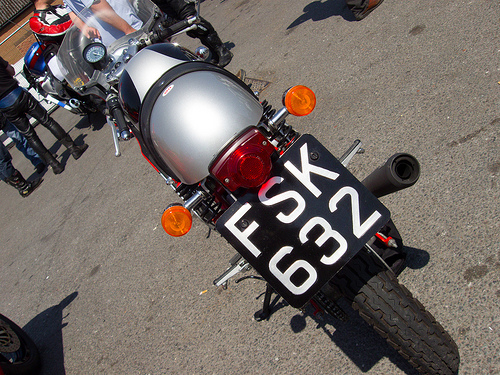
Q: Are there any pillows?
A: No, there are no pillows.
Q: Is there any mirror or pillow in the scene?
A: No, there are no pillows or mirrors.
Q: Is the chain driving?
A: Yes, the chain is driving.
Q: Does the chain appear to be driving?
A: Yes, the chain is driving.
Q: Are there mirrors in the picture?
A: No, there are no mirrors.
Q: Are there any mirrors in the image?
A: No, there are no mirrors.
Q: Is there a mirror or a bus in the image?
A: No, there are no mirrors or buses.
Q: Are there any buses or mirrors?
A: No, there are no mirrors or buses.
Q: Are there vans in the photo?
A: No, there are no vans.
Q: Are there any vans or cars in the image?
A: No, there are no vans or cars.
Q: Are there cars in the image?
A: No, there are no cars.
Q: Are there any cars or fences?
A: No, there are no cars or fences.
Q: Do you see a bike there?
A: Yes, there is a bike.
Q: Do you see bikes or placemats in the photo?
A: Yes, there is a bike.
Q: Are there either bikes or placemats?
A: Yes, there is a bike.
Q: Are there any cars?
A: No, there are no cars.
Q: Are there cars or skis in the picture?
A: No, there are no cars or skis.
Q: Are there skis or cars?
A: No, there are no cars or skis.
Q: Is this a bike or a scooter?
A: This is a bike.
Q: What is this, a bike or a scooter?
A: This is a bike.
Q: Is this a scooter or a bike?
A: This is a bike.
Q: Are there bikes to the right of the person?
A: Yes, there is a bike to the right of the person.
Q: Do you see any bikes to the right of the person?
A: Yes, there is a bike to the right of the person.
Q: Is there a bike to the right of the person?
A: Yes, there is a bike to the right of the person.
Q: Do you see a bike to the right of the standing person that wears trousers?
A: Yes, there is a bike to the right of the person.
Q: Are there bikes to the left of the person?
A: No, the bike is to the right of the person.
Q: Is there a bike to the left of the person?
A: No, the bike is to the right of the person.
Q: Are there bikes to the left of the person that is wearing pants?
A: No, the bike is to the right of the person.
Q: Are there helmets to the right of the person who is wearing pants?
A: No, there is a bike to the right of the person.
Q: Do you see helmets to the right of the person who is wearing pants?
A: No, there is a bike to the right of the person.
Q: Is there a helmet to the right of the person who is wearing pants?
A: No, there is a bike to the right of the person.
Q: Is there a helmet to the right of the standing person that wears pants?
A: No, there is a bike to the right of the person.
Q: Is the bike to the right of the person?
A: Yes, the bike is to the right of the person.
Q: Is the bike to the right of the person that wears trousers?
A: Yes, the bike is to the right of the person.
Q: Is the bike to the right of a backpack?
A: No, the bike is to the right of the person.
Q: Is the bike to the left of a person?
A: No, the bike is to the right of a person.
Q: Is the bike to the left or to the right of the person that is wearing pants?
A: The bike is to the right of the person.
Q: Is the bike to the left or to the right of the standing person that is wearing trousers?
A: The bike is to the right of the person.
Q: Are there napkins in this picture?
A: No, there are no napkins.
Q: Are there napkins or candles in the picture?
A: No, there are no napkins or candles.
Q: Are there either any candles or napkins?
A: No, there are no napkins or candles.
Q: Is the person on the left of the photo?
A: Yes, the person is on the left of the image.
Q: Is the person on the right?
A: No, the person is on the left of the image.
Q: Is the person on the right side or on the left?
A: The person is on the left of the image.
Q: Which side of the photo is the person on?
A: The person is on the left of the image.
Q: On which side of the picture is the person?
A: The person is on the left of the image.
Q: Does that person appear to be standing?
A: Yes, the person is standing.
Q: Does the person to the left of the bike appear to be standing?
A: Yes, the person is standing.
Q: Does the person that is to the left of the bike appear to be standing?
A: Yes, the person is standing.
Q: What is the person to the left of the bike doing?
A: The person is standing.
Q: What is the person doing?
A: The person is standing.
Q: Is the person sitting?
A: No, the person is standing.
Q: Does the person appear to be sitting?
A: No, the person is standing.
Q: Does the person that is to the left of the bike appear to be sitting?
A: No, the person is standing.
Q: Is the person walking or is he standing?
A: The person is standing.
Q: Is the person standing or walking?
A: The person is standing.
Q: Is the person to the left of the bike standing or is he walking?
A: The person is standing.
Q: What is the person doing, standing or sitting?
A: The person is standing.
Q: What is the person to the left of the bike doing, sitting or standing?
A: The person is standing.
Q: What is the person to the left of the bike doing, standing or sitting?
A: The person is standing.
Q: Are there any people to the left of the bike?
A: Yes, there is a person to the left of the bike.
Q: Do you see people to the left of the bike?
A: Yes, there is a person to the left of the bike.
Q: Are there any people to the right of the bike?
A: No, the person is to the left of the bike.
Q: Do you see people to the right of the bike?
A: No, the person is to the left of the bike.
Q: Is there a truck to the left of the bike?
A: No, there is a person to the left of the bike.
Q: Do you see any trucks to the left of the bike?
A: No, there is a person to the left of the bike.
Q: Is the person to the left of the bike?
A: Yes, the person is to the left of the bike.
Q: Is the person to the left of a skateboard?
A: No, the person is to the left of the bike.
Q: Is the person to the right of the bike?
A: No, the person is to the left of the bike.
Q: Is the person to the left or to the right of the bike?
A: The person is to the left of the bike.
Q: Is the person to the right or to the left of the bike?
A: The person is to the left of the bike.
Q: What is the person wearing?
A: The person is wearing trousers.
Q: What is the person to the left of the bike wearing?
A: The person is wearing trousers.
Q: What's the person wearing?
A: The person is wearing trousers.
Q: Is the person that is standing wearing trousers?
A: Yes, the person is wearing trousers.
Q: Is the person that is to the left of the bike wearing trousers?
A: Yes, the person is wearing trousers.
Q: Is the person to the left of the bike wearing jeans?
A: No, the person is wearing trousers.